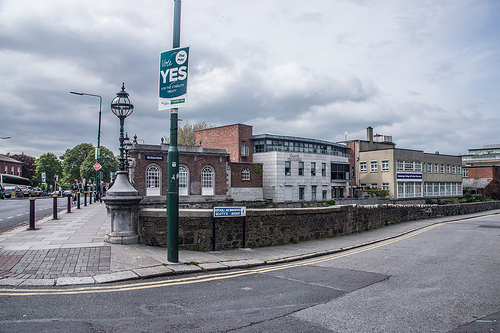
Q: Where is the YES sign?
A: On a metal pole.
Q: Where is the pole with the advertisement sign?
A: On the sidewalk.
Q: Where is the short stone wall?
A: By the sidewalk.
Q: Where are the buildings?
A: Behind the short wall.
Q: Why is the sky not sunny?
A: Lots of clouds.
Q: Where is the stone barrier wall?
A: Along the sidewalk.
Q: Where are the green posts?
A: Along the street on the sidewalk.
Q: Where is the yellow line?
A: On the street next to the curb.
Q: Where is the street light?
A: At the corner on the brick pedestal.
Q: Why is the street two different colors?
A: It has been patched.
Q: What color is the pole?
A: Green.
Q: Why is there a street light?
A: For when it is dark.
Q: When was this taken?
A: During the day.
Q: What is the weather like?
A: Cloudy.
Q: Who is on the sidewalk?
A: No one.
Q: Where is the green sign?
A: On the corner.